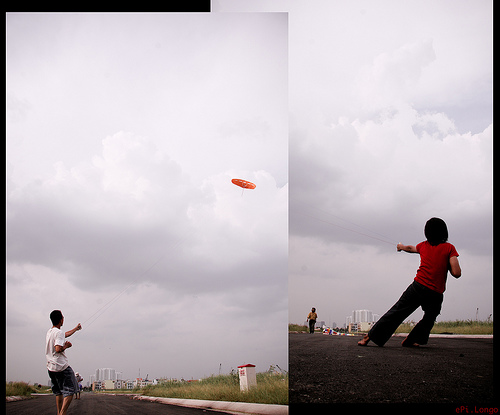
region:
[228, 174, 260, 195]
an orange kite in the air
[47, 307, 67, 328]
the head of a man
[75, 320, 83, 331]
the hand of a man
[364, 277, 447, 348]
a person's black pants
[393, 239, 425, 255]
a person's arm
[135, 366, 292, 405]
a patch of green grass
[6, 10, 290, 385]
a cloudy gray sky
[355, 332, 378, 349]
the foot of a person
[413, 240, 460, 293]
a person's red shirt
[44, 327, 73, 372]
a white tee shirt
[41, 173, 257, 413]
a boy flying a kite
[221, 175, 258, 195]
the kite is orange up in the sky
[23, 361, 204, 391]
tall buildings are in the distance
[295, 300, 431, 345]
buildings are at the end of the road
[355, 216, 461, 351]
a person flying a kite leaning to the side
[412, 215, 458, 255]
the person has long black hair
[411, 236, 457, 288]
a person is wearing a red shirt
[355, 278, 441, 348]
the person is barefoot and wearing black bell bottoms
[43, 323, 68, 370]
the boy is wearing a white t-shirt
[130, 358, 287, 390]
construction cranes are on the skyline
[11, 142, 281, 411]
this man is flying something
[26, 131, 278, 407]
the man is wearing a white shirt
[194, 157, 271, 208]
the object he is flying could be a kite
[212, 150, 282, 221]
the object in the sky is orange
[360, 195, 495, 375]
this person is wearing black pants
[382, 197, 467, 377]
this person is wearing a red shirt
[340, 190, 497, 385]
this person appears to be flying something too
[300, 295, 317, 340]
the man is wearing a yellow shirt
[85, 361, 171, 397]
there are tall building in the back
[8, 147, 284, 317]
the sky looks very cloudy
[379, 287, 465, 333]
the pants are black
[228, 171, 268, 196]
the kite is in the air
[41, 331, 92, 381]
the top is white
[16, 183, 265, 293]
the sky is cloudy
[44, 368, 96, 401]
the jeans are grey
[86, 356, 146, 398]
there are buildings in the background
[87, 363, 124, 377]
the buildings are white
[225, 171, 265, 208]
the kite is orange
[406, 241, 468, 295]
the top is red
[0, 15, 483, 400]
the photo is a daytime one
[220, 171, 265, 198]
orange kite in air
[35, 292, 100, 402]
boy in white t shirt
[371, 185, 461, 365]
person in red t-shirt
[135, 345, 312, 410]
grass field next to the road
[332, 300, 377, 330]
tall buildings in the background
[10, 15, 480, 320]
grey clouds in the sky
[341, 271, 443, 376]
person has bare feet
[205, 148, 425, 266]
person is holding orange kite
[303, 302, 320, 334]
man with yellow shirt walking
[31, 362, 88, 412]
man wearing blue and black shorts